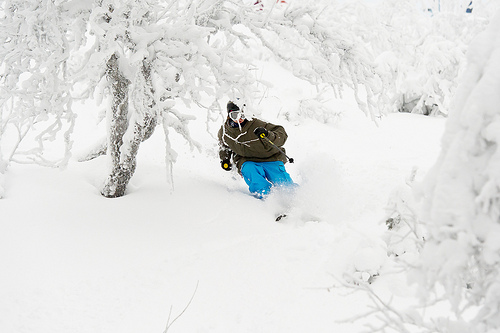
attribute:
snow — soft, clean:
[180, 35, 227, 91]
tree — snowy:
[81, 15, 167, 199]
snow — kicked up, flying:
[53, 184, 347, 281]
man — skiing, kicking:
[201, 88, 295, 201]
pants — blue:
[235, 159, 289, 197]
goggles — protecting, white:
[226, 110, 261, 123]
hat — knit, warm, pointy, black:
[221, 99, 241, 113]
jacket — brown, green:
[205, 126, 286, 163]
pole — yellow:
[256, 134, 301, 163]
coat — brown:
[196, 118, 296, 156]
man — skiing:
[204, 91, 290, 221]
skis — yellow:
[273, 197, 304, 228]